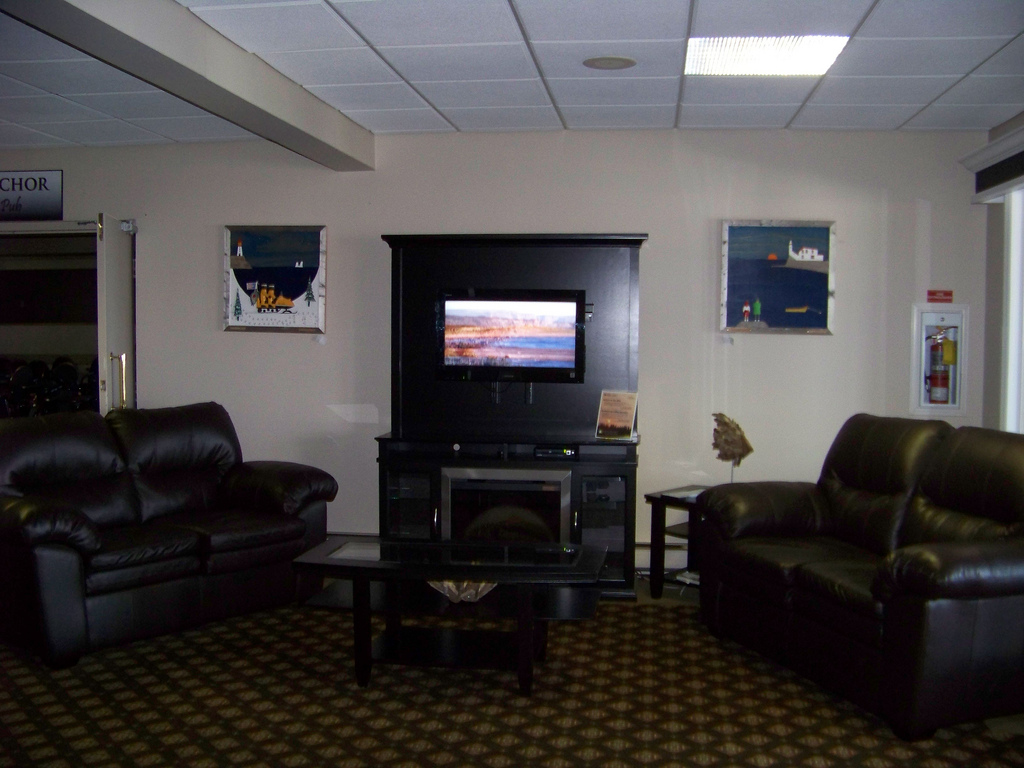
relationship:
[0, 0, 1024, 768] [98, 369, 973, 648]
living room with couches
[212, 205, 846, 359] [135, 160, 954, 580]
painting hanging wall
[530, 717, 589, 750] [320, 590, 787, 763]
design on carpet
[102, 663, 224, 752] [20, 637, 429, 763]
diamond on carpet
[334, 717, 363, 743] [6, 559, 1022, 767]
design on carpet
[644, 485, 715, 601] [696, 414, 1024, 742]
end table standing next to couch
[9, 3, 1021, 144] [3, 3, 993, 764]
ceiling covering living room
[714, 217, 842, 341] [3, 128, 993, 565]
picture hanging on wall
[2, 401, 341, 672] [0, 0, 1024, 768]
couch sitting inside living room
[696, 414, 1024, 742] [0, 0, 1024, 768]
couch sitting inside living room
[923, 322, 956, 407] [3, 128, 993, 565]
fire hydrant hanging on wall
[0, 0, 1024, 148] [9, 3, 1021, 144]
ceiling on ceiling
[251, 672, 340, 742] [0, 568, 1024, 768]
pattern on carpet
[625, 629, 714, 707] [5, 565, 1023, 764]
pattern on floor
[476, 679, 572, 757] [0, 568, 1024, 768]
pattern on carpet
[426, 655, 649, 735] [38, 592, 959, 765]
pattern on floor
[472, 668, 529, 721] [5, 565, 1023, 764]
pattern on floor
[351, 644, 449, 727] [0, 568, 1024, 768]
pattern on carpet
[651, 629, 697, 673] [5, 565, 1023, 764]
pattern on floor